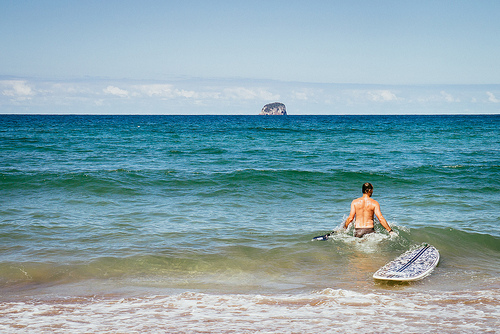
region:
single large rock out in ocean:
[238, 97, 307, 124]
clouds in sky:
[4, 71, 248, 111]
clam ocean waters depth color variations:
[23, 113, 163, 291]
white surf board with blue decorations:
[369, 230, 451, 288]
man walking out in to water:
[346, 182, 403, 242]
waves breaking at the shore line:
[88, 287, 434, 327]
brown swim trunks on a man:
[350, 225, 380, 239]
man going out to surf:
[306, 166, 465, 297]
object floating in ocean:
[296, 229, 343, 248]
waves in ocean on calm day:
[201, 155, 397, 182]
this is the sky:
[11, 7, 208, 85]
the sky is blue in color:
[85, 13, 165, 63]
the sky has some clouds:
[6, 73, 120, 98]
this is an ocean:
[102, 112, 252, 159]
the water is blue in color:
[94, 127, 174, 170]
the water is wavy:
[141, 152, 343, 198]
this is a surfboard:
[392, 250, 422, 282]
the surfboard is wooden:
[396, 256, 411, 268]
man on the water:
[349, 182, 378, 247]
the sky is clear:
[136, 55, 212, 82]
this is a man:
[340, 178, 385, 245]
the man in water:
[331, 177, 385, 249]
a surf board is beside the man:
[366, 235, 445, 287]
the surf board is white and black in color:
[368, 240, 442, 285]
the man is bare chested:
[353, 197, 375, 223]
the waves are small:
[11, 159, 280, 302]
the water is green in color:
[9, 120, 267, 190]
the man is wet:
[338, 187, 383, 234]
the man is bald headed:
[364, 180, 371, 186]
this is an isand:
[263, 101, 285, 111]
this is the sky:
[113, 8, 343, 68]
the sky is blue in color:
[148, 32, 310, 65]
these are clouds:
[106, 82, 191, 98]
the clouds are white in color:
[98, 78, 246, 102]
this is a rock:
[255, 100, 290, 117]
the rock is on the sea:
[255, 102, 294, 120]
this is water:
[119, 112, 271, 142]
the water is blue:
[128, 112, 256, 143]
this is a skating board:
[372, 238, 449, 286]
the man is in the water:
[351, 175, 396, 260]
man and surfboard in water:
[331, 165, 451, 290]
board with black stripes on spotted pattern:
[366, 205, 441, 290]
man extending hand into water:
[337, 181, 407, 241]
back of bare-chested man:
[335, 167, 395, 243]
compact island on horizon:
[190, 70, 366, 150]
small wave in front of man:
[270, 156, 460, 226]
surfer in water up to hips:
[330, 150, 395, 270]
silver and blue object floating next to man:
[301, 180, 376, 245]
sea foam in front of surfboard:
[300, 257, 471, 319]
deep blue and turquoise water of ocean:
[382, 113, 477, 168]